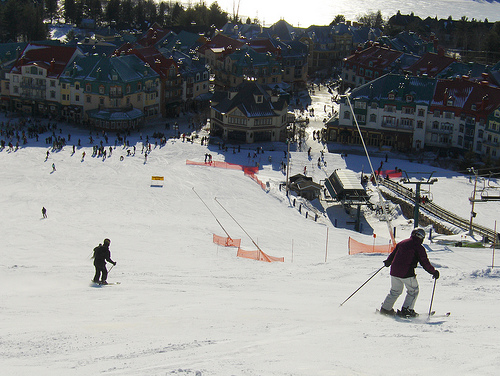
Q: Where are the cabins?
A: In back.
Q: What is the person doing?
A: Skiing.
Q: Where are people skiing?
A: In snow.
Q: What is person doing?
A: Skiing.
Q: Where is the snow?
A: On ground.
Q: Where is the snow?
A: On ground.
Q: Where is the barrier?
A: In snow.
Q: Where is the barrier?
A: In snow.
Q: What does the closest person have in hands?
A: Ski poles.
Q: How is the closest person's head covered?
A: Helmet.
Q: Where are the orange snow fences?
A: On the right of the slope.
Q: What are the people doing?
A: Skiing.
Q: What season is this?
A: Winter.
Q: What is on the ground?
A: Snow.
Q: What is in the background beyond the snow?
A: Houses.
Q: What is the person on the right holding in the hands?
A: Ski poles.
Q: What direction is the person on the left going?
A: Downhill.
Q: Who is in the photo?
A: People skiing.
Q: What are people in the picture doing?
A: Skiing.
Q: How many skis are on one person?
A: Two.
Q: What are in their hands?
A: Poles.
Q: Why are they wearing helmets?
A: For protection.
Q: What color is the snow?
A: White.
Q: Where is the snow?
A: On the ground.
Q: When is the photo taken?
A: During the day.